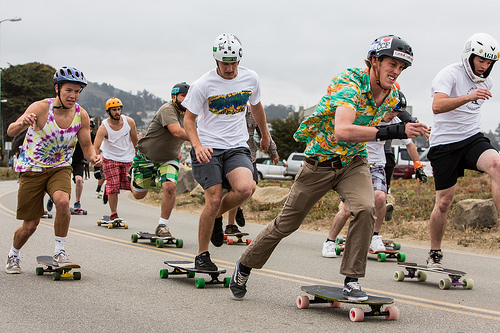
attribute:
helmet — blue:
[50, 63, 90, 91]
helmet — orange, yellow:
[105, 96, 123, 114]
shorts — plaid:
[101, 154, 135, 195]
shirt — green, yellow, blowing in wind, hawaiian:
[291, 66, 401, 170]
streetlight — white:
[0, 15, 25, 27]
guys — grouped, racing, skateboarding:
[5, 32, 499, 303]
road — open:
[1, 173, 499, 332]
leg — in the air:
[465, 138, 499, 220]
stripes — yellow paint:
[0, 183, 500, 323]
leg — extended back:
[235, 167, 331, 284]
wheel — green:
[194, 274, 208, 290]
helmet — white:
[214, 29, 245, 66]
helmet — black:
[168, 81, 197, 114]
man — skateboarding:
[182, 29, 274, 287]